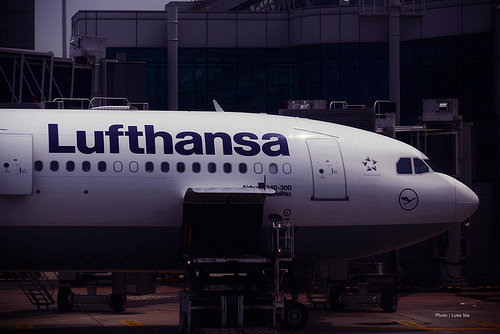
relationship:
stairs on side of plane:
[8, 266, 56, 313] [4, 92, 474, 309]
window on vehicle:
[207, 161, 215, 171] [0, 97, 494, 308]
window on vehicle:
[158, 160, 172, 175] [0, 97, 494, 308]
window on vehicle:
[144, 157, 156, 174] [0, 97, 494, 308]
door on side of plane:
[306, 136, 348, 201] [0, 97, 479, 324]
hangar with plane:
[0, 1, 429, 113] [7, 99, 482, 244]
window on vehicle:
[46, 152, 63, 178] [0, 97, 494, 308]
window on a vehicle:
[81, 160, 91, 172] [0, 97, 494, 308]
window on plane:
[81, 160, 91, 172] [4, 92, 474, 309]